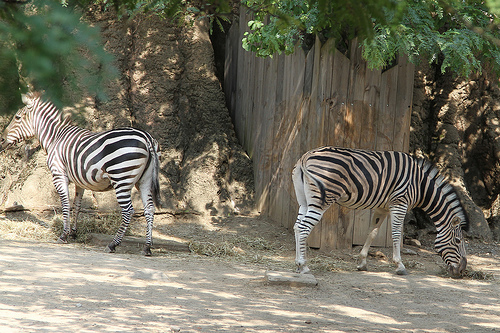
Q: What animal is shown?
A: Zebra.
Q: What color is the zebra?
A: Black, white.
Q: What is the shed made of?
A: Wood.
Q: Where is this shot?
A: Zoo.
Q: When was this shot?
A: Daytime.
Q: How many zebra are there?
A: 2.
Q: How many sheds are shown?
A: 1.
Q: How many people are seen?
A: 0.